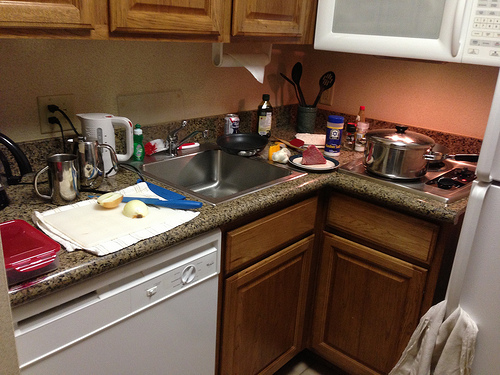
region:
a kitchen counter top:
[221, 81, 444, 237]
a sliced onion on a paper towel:
[75, 186, 163, 250]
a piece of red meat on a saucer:
[291, 142, 342, 181]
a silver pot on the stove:
[365, 118, 442, 178]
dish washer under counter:
[34, 234, 235, 371]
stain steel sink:
[149, 126, 311, 208]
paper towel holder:
[207, 49, 288, 78]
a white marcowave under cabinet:
[304, 0, 499, 62]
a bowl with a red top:
[6, 210, 74, 287]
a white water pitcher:
[79, 100, 139, 175]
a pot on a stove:
[365, 122, 477, 179]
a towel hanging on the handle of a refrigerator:
[388, 290, 482, 373]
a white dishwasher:
[16, 225, 225, 374]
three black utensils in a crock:
[284, 57, 340, 133]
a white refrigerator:
[424, 75, 497, 373]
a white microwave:
[313, 1, 499, 70]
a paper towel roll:
[209, 42, 278, 88]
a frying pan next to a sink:
[218, 129, 271, 158]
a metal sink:
[144, 128, 297, 199]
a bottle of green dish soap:
[130, 116, 145, 165]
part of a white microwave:
[313, 0, 498, 78]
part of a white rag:
[386, 297, 483, 372]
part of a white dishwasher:
[9, 229, 219, 373]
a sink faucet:
[159, 113, 212, 159]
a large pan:
[356, 122, 448, 185]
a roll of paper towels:
[216, 51, 268, 78]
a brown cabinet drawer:
[323, 192, 435, 262]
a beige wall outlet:
[36, 90, 80, 133]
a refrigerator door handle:
[439, 178, 486, 311]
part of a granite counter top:
[308, 110, 485, 222]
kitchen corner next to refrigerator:
[6, 7, 491, 354]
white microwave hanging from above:
[306, 0, 496, 65]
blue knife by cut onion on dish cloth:
[40, 180, 201, 255]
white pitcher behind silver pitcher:
[70, 105, 135, 190]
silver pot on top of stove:
[336, 106, 476, 201]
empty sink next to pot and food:
[137, 121, 332, 211]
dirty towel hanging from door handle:
[385, 271, 475, 371]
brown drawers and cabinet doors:
[220, 177, 437, 367]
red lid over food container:
[1, 210, 61, 285]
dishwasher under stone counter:
[15, 225, 230, 371]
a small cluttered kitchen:
[14, 5, 479, 342]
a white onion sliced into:
[94, 189, 139, 222]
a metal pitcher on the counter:
[46, 148, 78, 207]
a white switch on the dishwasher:
[144, 280, 162, 297]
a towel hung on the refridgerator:
[416, 312, 475, 366]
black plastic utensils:
[283, 60, 331, 105]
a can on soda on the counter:
[216, 110, 236, 130]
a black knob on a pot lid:
[397, 117, 411, 136]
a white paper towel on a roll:
[227, 49, 265, 78]